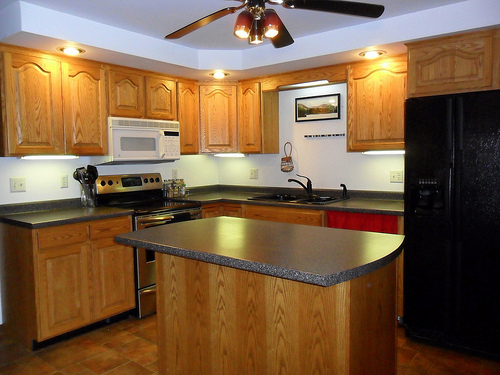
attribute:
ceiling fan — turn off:
[157, 0, 393, 54]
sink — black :
[246, 185, 343, 210]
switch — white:
[9, 174, 29, 196]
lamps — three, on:
[46, 43, 426, 68]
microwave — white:
[90, 116, 180, 163]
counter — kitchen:
[115, 195, 420, 305]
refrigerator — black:
[403, 89, 499, 361]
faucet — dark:
[268, 168, 351, 243]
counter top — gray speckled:
[111, 212, 406, 287]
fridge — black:
[402, 90, 485, 349]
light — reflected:
[224, 19, 292, 48]